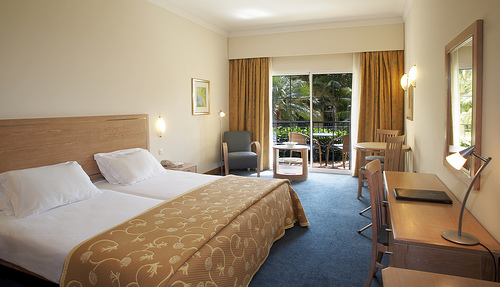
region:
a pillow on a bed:
[14, 150, 114, 227]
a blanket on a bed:
[68, 128, 303, 275]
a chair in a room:
[215, 120, 270, 182]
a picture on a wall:
[186, 59, 248, 121]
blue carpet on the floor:
[281, 136, 378, 267]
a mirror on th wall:
[434, 20, 494, 176]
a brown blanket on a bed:
[84, 111, 340, 272]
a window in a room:
[255, 66, 392, 166]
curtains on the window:
[221, 61, 277, 153]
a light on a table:
[435, 133, 495, 243]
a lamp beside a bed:
[132, 111, 172, 171]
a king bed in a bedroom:
[0, 105, 304, 284]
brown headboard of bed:
[0, 96, 169, 199]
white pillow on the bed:
[91, 130, 178, 190]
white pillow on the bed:
[1, 148, 103, 221]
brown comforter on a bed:
[76, 160, 318, 284]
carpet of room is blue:
[278, 169, 366, 278]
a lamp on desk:
[416, 130, 495, 254]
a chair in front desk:
[352, 150, 428, 262]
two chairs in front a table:
[351, 120, 419, 166]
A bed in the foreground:
[0, 108, 308, 281]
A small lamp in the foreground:
[422, 131, 491, 254]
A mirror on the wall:
[423, 16, 488, 191]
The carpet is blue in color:
[231, 163, 383, 285]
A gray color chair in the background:
[212, 119, 264, 179]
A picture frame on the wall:
[183, 72, 214, 120]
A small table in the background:
[270, 130, 315, 189]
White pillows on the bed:
[1, 132, 165, 224]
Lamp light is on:
[441, 132, 473, 176]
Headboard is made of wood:
[3, 102, 168, 186]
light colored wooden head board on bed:
[0, 112, 151, 179]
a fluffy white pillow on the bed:
[0, 158, 103, 220]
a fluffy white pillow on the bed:
[93, 145, 165, 185]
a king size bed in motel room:
[0, 113, 309, 285]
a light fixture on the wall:
[154, 113, 168, 135]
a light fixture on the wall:
[400, 62, 420, 86]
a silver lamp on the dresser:
[440, 142, 491, 244]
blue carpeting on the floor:
[213, 167, 390, 284]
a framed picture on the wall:
[190, 77, 210, 114]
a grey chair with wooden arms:
[220, 130, 260, 177]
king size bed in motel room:
[2, 112, 307, 285]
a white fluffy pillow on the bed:
[1, 160, 101, 217]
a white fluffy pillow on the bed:
[93, 148, 166, 186]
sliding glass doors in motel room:
[270, 71, 353, 170]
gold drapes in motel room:
[227, 49, 404, 176]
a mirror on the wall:
[443, 14, 490, 189]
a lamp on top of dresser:
[442, 143, 492, 245]